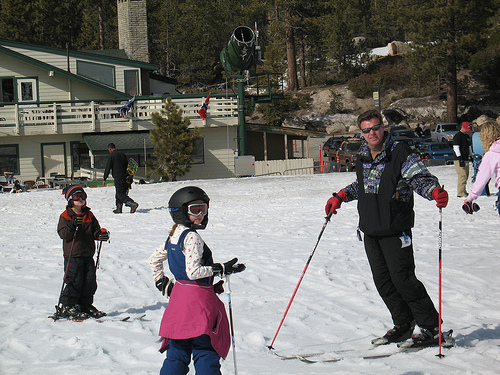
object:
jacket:
[156, 279, 232, 361]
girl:
[146, 184, 243, 373]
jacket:
[55, 208, 109, 254]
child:
[50, 183, 110, 320]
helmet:
[166, 187, 212, 230]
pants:
[364, 231, 442, 331]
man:
[322, 102, 455, 349]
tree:
[72, 0, 112, 49]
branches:
[155, 56, 182, 77]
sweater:
[462, 141, 499, 207]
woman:
[459, 123, 500, 216]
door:
[43, 144, 66, 185]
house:
[0, 44, 313, 191]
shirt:
[101, 153, 134, 182]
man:
[99, 142, 139, 215]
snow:
[0, 157, 500, 373]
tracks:
[133, 260, 161, 304]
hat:
[60, 184, 90, 201]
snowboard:
[122, 157, 145, 188]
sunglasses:
[357, 123, 385, 134]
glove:
[323, 197, 343, 215]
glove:
[432, 184, 448, 209]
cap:
[462, 121, 471, 133]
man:
[449, 120, 473, 197]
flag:
[198, 92, 215, 121]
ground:
[4, 159, 500, 374]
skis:
[271, 327, 459, 367]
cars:
[426, 121, 464, 141]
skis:
[46, 306, 151, 325]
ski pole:
[266, 210, 338, 349]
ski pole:
[435, 207, 448, 362]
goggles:
[185, 200, 210, 216]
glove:
[218, 257, 251, 277]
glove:
[154, 275, 173, 295]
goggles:
[67, 190, 92, 200]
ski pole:
[53, 218, 82, 320]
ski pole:
[92, 226, 110, 269]